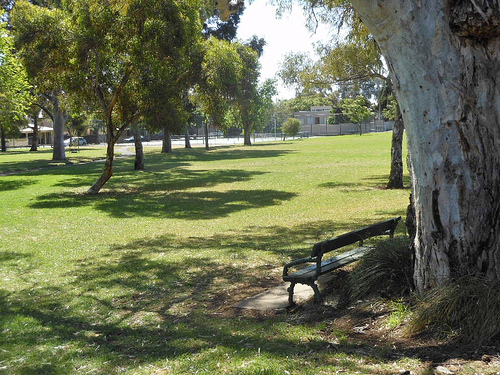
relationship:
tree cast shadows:
[15, 1, 244, 207] [0, 136, 296, 221]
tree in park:
[15, 1, 244, 207] [4, 3, 498, 371]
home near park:
[7, 123, 54, 149] [4, 3, 498, 371]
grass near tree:
[350, 237, 499, 350] [360, 5, 498, 293]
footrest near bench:
[234, 272, 342, 314] [278, 216, 404, 304]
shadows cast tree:
[0, 136, 296, 221] [15, 1, 244, 207]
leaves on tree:
[1, 0, 273, 136] [15, 1, 244, 207]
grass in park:
[9, 131, 412, 372] [4, 3, 498, 371]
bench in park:
[278, 216, 404, 304] [4, 3, 498, 371]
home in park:
[7, 123, 54, 149] [4, 3, 498, 371]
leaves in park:
[1, 0, 273, 136] [4, 3, 498, 371]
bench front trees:
[278, 216, 404, 304] [360, 5, 498, 293]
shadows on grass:
[0, 136, 296, 221] [9, 131, 412, 372]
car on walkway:
[61, 138, 86, 149] [4, 140, 133, 186]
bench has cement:
[278, 216, 404, 304] [234, 272, 342, 314]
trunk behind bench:
[360, 5, 498, 293] [278, 216, 404, 304]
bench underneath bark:
[278, 216, 404, 304] [360, 5, 498, 293]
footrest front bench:
[234, 272, 342, 314] [278, 216, 404, 304]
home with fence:
[7, 123, 54, 149] [294, 122, 398, 137]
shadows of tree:
[0, 136, 296, 221] [15, 1, 244, 207]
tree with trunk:
[15, 1, 245, 199] [85, 97, 122, 201]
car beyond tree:
[61, 138, 86, 149] [15, 1, 244, 207]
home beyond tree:
[7, 123, 54, 149] [15, 1, 244, 207]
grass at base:
[350, 237, 499, 350] [403, 236, 500, 289]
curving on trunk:
[95, 152, 116, 192] [85, 97, 122, 201]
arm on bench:
[280, 259, 318, 283] [278, 216, 404, 304]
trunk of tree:
[85, 97, 122, 201] [15, 1, 245, 199]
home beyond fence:
[7, 123, 54, 149] [294, 122, 398, 137]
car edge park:
[61, 138, 86, 149] [4, 3, 498, 371]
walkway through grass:
[4, 140, 133, 186] [9, 131, 412, 372]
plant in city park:
[4, 3, 498, 371] [6, 140, 491, 372]